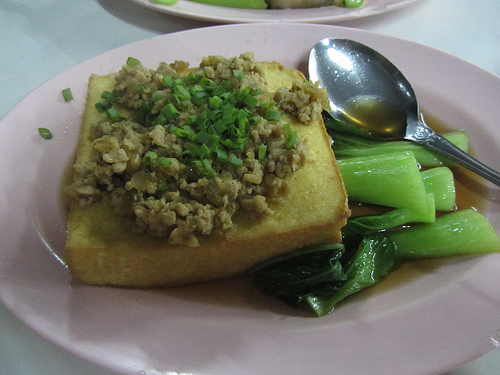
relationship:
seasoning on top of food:
[148, 84, 273, 187] [191, 99, 491, 314]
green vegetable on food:
[270, 154, 427, 333] [108, 99, 324, 349]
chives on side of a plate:
[30, 77, 77, 141] [84, 326, 194, 375]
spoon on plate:
[306, 36, 498, 186] [71, 285, 488, 375]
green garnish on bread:
[170, 81, 256, 163] [241, 164, 323, 255]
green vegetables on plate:
[329, 139, 464, 263] [99, 265, 492, 375]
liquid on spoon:
[334, 91, 407, 141] [333, 101, 431, 187]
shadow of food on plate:
[33, 305, 213, 348] [281, 314, 464, 375]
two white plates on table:
[102, 50, 208, 53] [11, 343, 58, 375]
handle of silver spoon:
[434, 139, 481, 171] [361, 99, 401, 139]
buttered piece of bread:
[164, 161, 326, 248] [90, 129, 111, 339]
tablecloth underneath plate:
[14, 50, 34, 90] [21, 335, 48, 375]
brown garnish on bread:
[102, 120, 288, 229] [283, 165, 331, 253]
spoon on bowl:
[306, 36, 498, 186] [277, 265, 472, 375]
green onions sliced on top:
[174, 85, 270, 168] [93, 167, 274, 304]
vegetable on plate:
[245, 207, 484, 317] [319, 307, 458, 375]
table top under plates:
[13, 52, 43, 84] [12, 99, 97, 318]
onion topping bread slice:
[210, 148, 230, 162] [62, 57, 352, 288]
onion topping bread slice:
[195, 139, 212, 159] [62, 57, 352, 288]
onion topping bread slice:
[262, 108, 281, 121] [62, 57, 352, 288]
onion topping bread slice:
[140, 147, 158, 166] [62, 57, 352, 288]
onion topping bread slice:
[160, 100, 179, 120] [62, 57, 352, 288]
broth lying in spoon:
[337, 94, 407, 143] [306, 36, 498, 186]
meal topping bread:
[60, 51, 485, 316] [61, 57, 350, 287]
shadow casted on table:
[98, 1, 222, 33] [2, 1, 484, 371]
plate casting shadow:
[128, 1, 415, 21] [98, 1, 222, 33]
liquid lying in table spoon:
[334, 91, 407, 141] [306, 36, 485, 177]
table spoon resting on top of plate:
[306, 36, 485, 177] [1, 20, 481, 372]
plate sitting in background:
[128, 1, 415, 21] [1, 1, 484, 22]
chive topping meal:
[140, 149, 157, 169] [60, 57, 350, 288]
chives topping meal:
[164, 72, 250, 169] [60, 57, 350, 288]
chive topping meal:
[255, 141, 269, 161] [60, 57, 350, 288]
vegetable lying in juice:
[245, 207, 484, 317] [155, 105, 485, 318]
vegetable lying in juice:
[339, 190, 438, 235] [155, 105, 485, 318]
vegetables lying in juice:
[349, 139, 448, 274] [155, 105, 485, 318]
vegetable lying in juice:
[326, 129, 470, 169] [155, 105, 485, 318]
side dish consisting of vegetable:
[243, 109, 484, 318] [245, 207, 484, 317]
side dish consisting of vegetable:
[243, 109, 484, 318] [339, 190, 438, 235]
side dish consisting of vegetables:
[243, 109, 484, 318] [349, 139, 448, 274]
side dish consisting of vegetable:
[243, 109, 484, 318] [326, 129, 470, 169]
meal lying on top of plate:
[60, 51, 485, 316] [1, 20, 481, 372]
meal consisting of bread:
[60, 51, 485, 316] [61, 57, 350, 287]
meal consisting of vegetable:
[60, 51, 485, 316] [240, 114, 482, 313]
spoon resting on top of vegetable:
[306, 36, 498, 186] [325, 119, 470, 169]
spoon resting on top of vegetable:
[306, 36, 498, 186] [320, 110, 374, 137]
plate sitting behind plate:
[128, 1, 415, 21] [1, 20, 481, 372]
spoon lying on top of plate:
[306, 36, 498, 186] [1, 20, 481, 372]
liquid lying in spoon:
[334, 91, 407, 141] [306, 36, 498, 186]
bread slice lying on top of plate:
[62, 57, 352, 288] [1, 20, 481, 372]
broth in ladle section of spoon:
[337, 94, 407, 143] [306, 36, 498, 186]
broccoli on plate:
[315, 127, 498, 301] [1, 20, 481, 372]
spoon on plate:
[306, 36, 498, 186] [1, 20, 481, 372]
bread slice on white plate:
[62, 57, 352, 288] [0, 20, 480, 368]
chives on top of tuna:
[164, 72, 250, 169] [84, 119, 264, 240]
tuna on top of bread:
[100, 66, 301, 236] [61, 57, 350, 287]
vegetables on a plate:
[349, 139, 448, 274] [1, 20, 481, 372]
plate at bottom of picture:
[1, 20, 481, 372] [0, 1, 484, 371]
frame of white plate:
[209, 9, 327, 20] [136, 1, 419, 18]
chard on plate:
[330, 135, 473, 313] [1, 20, 481, 372]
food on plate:
[73, 60, 484, 301] [1, 20, 481, 372]